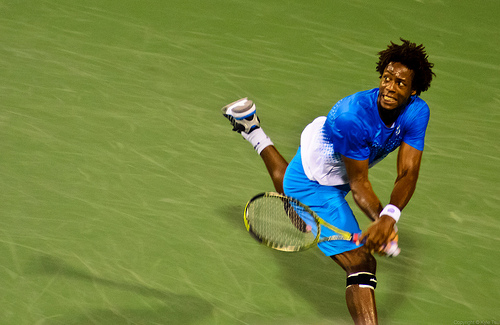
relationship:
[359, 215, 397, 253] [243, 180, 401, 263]
hands holding racket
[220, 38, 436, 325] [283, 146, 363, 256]
man wearing shorts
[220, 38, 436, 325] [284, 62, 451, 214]
man wearing a shirt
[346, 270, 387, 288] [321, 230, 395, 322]
band around leg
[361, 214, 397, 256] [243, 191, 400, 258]
hands holding racket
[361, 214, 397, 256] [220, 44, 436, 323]
hands on man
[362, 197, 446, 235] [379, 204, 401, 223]
band on band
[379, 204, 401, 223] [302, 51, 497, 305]
band on man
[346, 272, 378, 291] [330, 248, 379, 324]
band on leg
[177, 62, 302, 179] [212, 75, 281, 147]
shoes on feet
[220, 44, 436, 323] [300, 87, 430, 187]
man wearing shirt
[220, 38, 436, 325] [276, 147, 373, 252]
man wearing shorts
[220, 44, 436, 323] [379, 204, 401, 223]
man wearing band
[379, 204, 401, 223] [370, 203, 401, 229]
band on wrist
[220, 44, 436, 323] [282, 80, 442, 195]
man wearing shirt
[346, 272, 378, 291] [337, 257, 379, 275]
band around man's knee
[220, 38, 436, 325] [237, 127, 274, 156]
man wearing socks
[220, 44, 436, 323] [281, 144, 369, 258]
man wearing shorts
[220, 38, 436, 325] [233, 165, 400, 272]
man holding racket